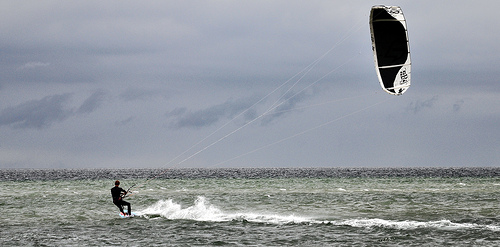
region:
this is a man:
[104, 174, 141, 217]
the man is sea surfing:
[96, 172, 140, 218]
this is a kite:
[359, 7, 419, 88]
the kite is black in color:
[358, 11, 416, 96]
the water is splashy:
[185, 187, 215, 213]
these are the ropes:
[225, 87, 290, 154]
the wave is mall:
[258, 197, 326, 242]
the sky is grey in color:
[75, 15, 206, 91]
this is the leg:
[123, 198, 134, 213]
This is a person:
[106, 165, 146, 233]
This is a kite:
[364, 2, 431, 107]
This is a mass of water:
[186, 172, 266, 223]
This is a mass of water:
[325, 174, 417, 227]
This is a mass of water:
[174, 161, 281, 209]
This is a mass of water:
[310, 171, 424, 213]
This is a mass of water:
[186, 205, 322, 230]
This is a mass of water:
[19, 169, 95, 199]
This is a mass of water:
[254, 210, 359, 244]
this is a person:
[102, 165, 148, 228]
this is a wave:
[150, 176, 235, 229]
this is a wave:
[223, 195, 315, 236]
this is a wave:
[352, 202, 397, 229]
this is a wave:
[419, 210, 475, 240]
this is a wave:
[137, 184, 175, 224]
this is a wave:
[234, 165, 271, 197]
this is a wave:
[311, 159, 388, 210]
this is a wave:
[238, 184, 308, 222]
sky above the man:
[117, 45, 192, 105]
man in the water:
[90, 170, 145, 225]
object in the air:
[340, 2, 445, 114]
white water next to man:
[180, 195, 220, 225]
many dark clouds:
[35, 35, 117, 105]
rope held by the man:
[126, 162, 163, 198]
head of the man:
[105, 171, 126, 186]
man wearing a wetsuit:
[91, 166, 141, 218]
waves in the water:
[52, 215, 108, 245]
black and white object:
[351, 6, 431, 116]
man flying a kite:
[104, 173, 142, 214]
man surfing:
[107, 181, 139, 214]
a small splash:
[154, 195, 221, 217]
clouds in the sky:
[18, 99, 104, 125]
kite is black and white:
[357, 8, 442, 107]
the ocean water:
[372, 165, 465, 218]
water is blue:
[302, 175, 396, 219]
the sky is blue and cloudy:
[175, 12, 291, 58]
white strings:
[250, 82, 325, 137]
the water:
[15, 193, 75, 238]